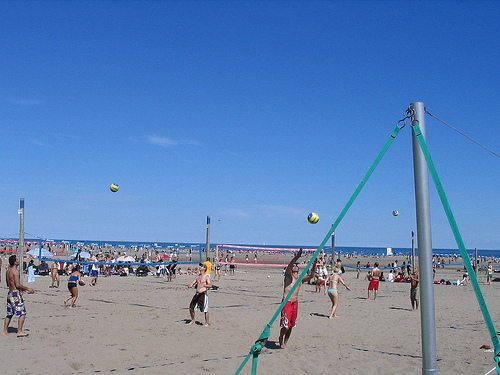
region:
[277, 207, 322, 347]
man is catching the volleyball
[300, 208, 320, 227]
the volleyball is blue and yellow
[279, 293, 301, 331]
man's shorts are red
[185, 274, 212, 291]
man not wearing a shirt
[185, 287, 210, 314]
man's shorts are black and white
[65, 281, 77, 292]
woman's bikini is black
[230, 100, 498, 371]
green straps on the pole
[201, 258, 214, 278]
man's shirt is yellow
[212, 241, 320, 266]
the net is red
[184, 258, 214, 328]
man is wearing a hat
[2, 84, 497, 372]
Beach with multiple volleyball games happening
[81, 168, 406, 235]
Brightly colored volleyballs in the air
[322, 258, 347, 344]
Young girl with blonde hair in sky blue bikini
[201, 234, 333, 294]
Pink volleyball net on beach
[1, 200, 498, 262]
Blue ocean in the distance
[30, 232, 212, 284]
Blue volleyball net on beach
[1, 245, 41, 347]
Young man in tiled blue yellow and white swim trunks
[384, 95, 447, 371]
Silver pole to hold net erect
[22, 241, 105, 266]
Two light blue beach umbrellas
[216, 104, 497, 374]
Green strap tie downs of volleyball net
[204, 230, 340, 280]
a yellow volleyball net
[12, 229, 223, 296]
a blue volleyball net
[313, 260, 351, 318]
a woman wearing a green bikini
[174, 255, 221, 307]
a man wearing a hat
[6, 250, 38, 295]
a man wearing no shirt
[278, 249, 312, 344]
a man wearing red swim shorts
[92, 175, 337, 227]
two volleyballs in the air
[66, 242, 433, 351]
people on the sand at the beach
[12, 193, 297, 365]
people playing volleyball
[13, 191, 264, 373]
people playing volleyball on the beach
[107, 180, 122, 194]
white ball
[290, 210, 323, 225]
white ball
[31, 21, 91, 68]
white clouds in blue sky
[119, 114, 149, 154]
white clouds in blue sky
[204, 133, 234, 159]
white clouds in blue sky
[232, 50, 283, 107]
white clouds in blue sky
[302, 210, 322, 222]
Volleyball in the air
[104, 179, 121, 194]
Volleyball flying through air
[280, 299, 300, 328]
Red shorts on man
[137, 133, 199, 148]
Wispy white cloud in sky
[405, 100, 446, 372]
Gray metal pole in sand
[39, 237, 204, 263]
Volleyball net with blue trim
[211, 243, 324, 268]
Volleyball net with pink trim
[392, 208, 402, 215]
Volleyball in the air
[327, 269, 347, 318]
Girl in green bikini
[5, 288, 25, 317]
Man in blue and tan checked shorts